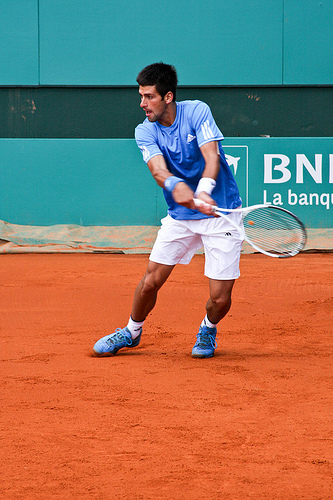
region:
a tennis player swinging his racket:
[84, 56, 312, 364]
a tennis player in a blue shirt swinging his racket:
[84, 53, 310, 357]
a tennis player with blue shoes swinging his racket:
[80, 55, 305, 356]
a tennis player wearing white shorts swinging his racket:
[83, 53, 306, 371]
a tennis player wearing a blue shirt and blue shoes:
[84, 56, 237, 359]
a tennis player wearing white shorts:
[84, 56, 251, 365]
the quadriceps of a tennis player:
[123, 255, 238, 304]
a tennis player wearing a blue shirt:
[117, 53, 308, 256]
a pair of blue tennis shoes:
[88, 320, 228, 359]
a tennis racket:
[172, 195, 311, 261]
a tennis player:
[93, 62, 307, 356]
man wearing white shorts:
[150, 206, 243, 279]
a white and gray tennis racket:
[194, 197, 308, 258]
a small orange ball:
[247, 219, 254, 225]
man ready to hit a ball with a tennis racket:
[93, 62, 306, 355]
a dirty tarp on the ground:
[0, 220, 332, 254]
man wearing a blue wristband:
[163, 177, 182, 191]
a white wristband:
[194, 177, 214, 196]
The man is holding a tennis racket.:
[86, 60, 311, 358]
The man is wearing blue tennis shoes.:
[86, 58, 310, 360]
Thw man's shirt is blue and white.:
[89, 58, 315, 359]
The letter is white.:
[259, 150, 292, 187]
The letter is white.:
[294, 150, 325, 186]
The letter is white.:
[258, 188, 271, 207]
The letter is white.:
[269, 189, 284, 206]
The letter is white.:
[283, 186, 298, 207]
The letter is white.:
[298, 191, 310, 208]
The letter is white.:
[308, 189, 319, 207]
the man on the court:
[95, 62, 284, 369]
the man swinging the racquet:
[78, 46, 320, 367]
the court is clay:
[5, 258, 330, 496]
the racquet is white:
[196, 193, 313, 269]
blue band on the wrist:
[156, 170, 178, 190]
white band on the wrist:
[188, 179, 217, 192]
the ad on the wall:
[220, 141, 331, 215]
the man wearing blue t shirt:
[124, 103, 248, 218]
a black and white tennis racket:
[189, 195, 306, 260]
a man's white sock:
[202, 316, 213, 326]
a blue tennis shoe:
[189, 318, 215, 355]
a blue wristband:
[158, 174, 181, 189]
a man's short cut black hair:
[133, 58, 179, 101]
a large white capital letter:
[260, 152, 291, 182]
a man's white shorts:
[144, 213, 242, 280]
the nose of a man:
[138, 95, 144, 106]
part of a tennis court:
[0, 254, 331, 498]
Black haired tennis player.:
[92, 61, 245, 357]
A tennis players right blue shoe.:
[91, 327, 142, 357]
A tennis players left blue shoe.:
[190, 320, 218, 359]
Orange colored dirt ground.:
[1, 252, 332, 498]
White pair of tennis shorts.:
[149, 205, 244, 281]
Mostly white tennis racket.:
[191, 197, 307, 258]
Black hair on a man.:
[135, 63, 177, 103]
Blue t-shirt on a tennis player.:
[135, 99, 241, 220]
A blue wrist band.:
[162, 174, 183, 193]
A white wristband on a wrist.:
[193, 177, 217, 198]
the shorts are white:
[148, 213, 242, 280]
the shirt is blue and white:
[134, 99, 241, 219]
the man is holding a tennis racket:
[94, 61, 305, 358]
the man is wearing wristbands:
[88, 61, 306, 358]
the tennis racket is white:
[191, 198, 307, 258]